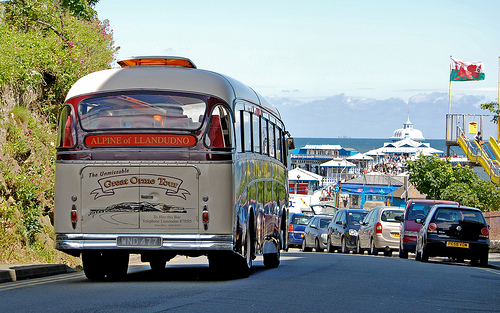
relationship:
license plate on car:
[446, 241, 469, 248] [416, 201, 491, 264]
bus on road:
[51, 55, 296, 282] [0, 236, 499, 308]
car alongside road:
[286, 213, 315, 253] [0, 236, 499, 308]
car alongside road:
[356, 206, 407, 255] [5, 241, 496, 310]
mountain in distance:
[269, 92, 491, 145] [3, 4, 499, 166]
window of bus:
[61, 94, 225, 157] [51, 55, 296, 282]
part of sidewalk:
[480, 245, 499, 269] [478, 237, 498, 260]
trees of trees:
[5, 4, 110, 70] [5, 4, 120, 272]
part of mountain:
[296, 98, 369, 135] [269, 92, 491, 145]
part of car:
[370, 212, 397, 227] [353, 199, 407, 260]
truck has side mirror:
[394, 199, 460, 259] [392, 210, 401, 221]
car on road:
[415, 204, 490, 266] [0, 236, 499, 308]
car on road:
[399, 198, 492, 248] [0, 236, 499, 308]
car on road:
[326, 209, 372, 253] [0, 236, 499, 308]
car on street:
[297, 206, 339, 253] [3, 236, 495, 307]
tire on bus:
[205, 203, 260, 281] [51, 55, 296, 282]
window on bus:
[78, 95, 207, 130] [45, 43, 319, 279]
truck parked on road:
[394, 195, 468, 264] [0, 236, 499, 308]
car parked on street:
[354, 193, 405, 253] [3, 236, 495, 307]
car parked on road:
[322, 207, 370, 254] [0, 236, 499, 308]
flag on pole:
[450, 56, 485, 81] [442, 50, 457, 143]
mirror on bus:
[282, 123, 297, 158] [51, 24, 323, 295]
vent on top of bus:
[109, 42, 202, 86] [45, 43, 319, 279]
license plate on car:
[445, 235, 474, 252] [409, 194, 493, 264]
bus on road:
[45, 43, 319, 279] [0, 236, 499, 308]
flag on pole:
[443, 46, 493, 96] [442, 43, 460, 147]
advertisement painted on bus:
[81, 164, 206, 236] [51, 55, 296, 282]